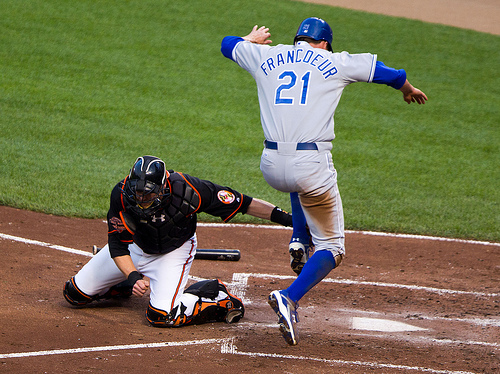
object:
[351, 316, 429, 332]
home plate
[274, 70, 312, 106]
number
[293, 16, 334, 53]
helmet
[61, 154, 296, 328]
catcher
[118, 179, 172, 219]
mask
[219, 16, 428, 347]
man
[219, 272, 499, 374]
batters box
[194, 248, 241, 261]
bat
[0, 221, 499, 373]
dirt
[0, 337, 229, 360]
chalk line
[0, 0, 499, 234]
grass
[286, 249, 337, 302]
socks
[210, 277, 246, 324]
sneaker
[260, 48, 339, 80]
name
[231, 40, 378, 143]
jersey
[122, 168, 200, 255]
chest protector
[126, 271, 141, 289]
wristband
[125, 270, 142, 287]
wrist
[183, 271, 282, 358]
lines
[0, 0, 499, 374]
field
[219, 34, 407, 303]
uniform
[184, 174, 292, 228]
arm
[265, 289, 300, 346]
footwear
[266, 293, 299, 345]
cleats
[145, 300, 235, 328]
pads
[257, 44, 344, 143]
back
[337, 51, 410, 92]
arm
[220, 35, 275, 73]
arm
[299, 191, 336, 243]
dirt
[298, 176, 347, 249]
thigh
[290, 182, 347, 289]
legs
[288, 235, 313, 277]
shoe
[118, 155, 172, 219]
helmet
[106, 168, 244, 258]
jersey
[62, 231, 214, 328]
pants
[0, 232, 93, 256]
line